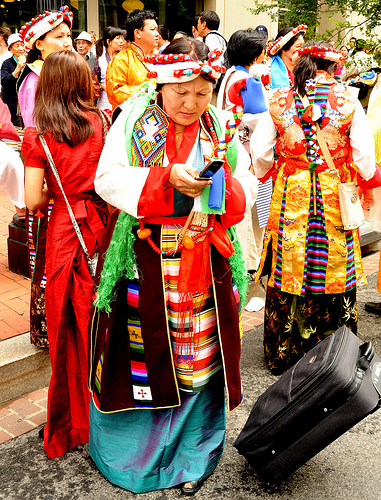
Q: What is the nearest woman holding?
A: A cell phone.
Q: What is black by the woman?
A: Suitcase with handles and wheels.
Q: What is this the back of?
A: Red haired woman in solid red long dress.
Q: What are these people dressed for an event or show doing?
A: Standing on the street.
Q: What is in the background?
A: Crowd mostly in native garb.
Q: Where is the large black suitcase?
A: Next to woman's foot.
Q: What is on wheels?
A: A black suitcase.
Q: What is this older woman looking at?
A: The phone.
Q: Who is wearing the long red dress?
A: A woman.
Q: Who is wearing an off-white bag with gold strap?
A: Woman on right.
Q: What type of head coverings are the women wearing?
A: Red, white and turquoise head dress.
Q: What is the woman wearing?
A: Tribal clothing.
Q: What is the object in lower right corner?
A: Black suitcase.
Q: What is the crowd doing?
A: Gathering to celebrate.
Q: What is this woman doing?
A: Looking at cell phone.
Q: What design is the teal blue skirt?
A: Long, plain.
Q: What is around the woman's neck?
A: Red beads.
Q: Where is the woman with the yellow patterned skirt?
A: Right of picture.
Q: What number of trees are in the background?
A: One.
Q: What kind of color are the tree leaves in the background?
A: Green.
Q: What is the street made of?
A: Asphalt.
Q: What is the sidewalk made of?
A: Brick.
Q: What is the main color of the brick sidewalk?
A: Red.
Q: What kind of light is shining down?
A: Sunlight.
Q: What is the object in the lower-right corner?
A: Luggage.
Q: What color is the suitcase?
A: Black.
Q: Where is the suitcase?
A: On the ground.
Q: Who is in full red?
A: A woman with brown hair.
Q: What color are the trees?
A: Green.